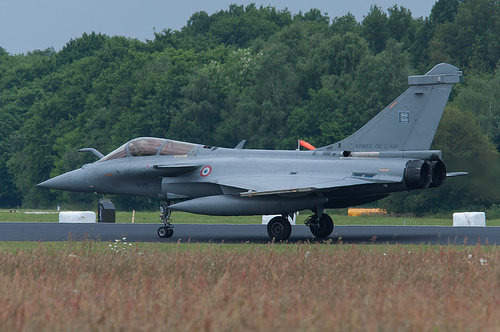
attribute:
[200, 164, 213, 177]
logo — red white, blue, red, white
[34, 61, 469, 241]
aircraft — gray, small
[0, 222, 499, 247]
runway — black, smooth, gray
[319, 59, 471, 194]
tail end — gray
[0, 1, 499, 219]
trees — large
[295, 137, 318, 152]
windsock — orange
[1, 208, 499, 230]
grass — dry, green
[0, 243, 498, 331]
grass — dry, green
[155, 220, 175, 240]
small wheel — black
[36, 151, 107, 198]
nose — pointy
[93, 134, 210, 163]
top — curved, clear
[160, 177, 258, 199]
front of wing — curved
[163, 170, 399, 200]
wing — triangular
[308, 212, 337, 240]
wheels — black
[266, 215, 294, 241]
wheels — black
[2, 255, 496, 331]
grass — brown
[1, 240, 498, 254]
grass — green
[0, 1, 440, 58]
sky — grayish blue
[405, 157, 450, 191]
exhaust pipes — black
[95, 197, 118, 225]
garbage can — small